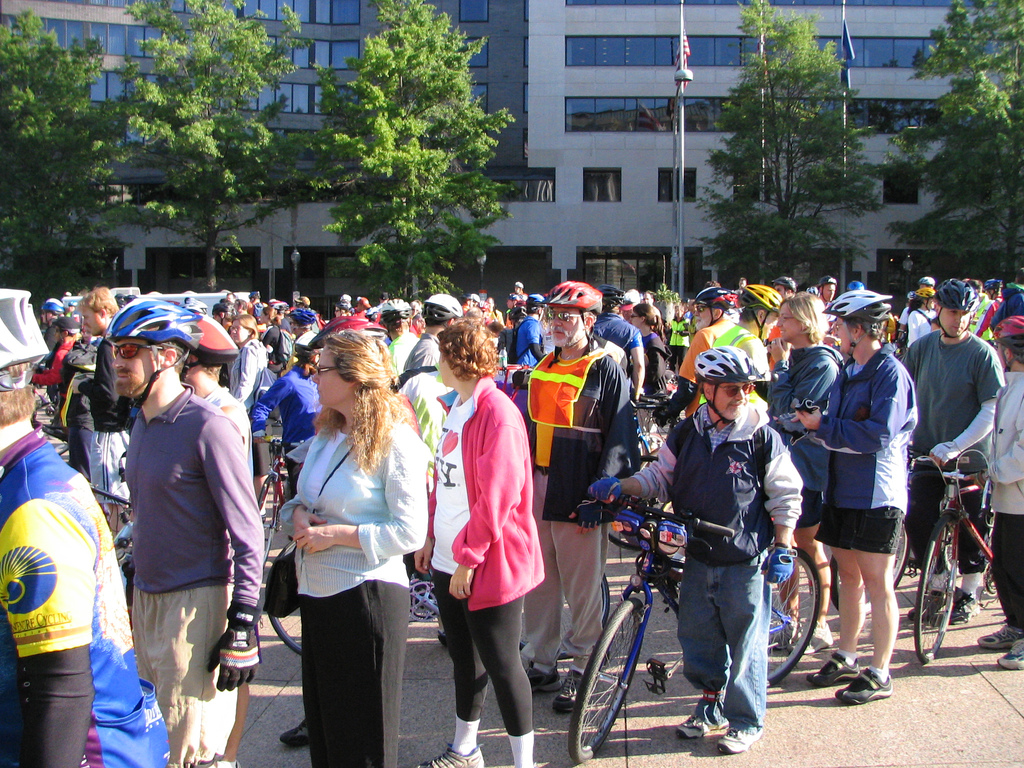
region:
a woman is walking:
[419, 322, 546, 766]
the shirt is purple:
[122, 390, 260, 603]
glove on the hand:
[210, 603, 259, 689]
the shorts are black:
[819, 501, 903, 556]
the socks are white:
[453, 717, 537, 766]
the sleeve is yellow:
[0, 504, 95, 656]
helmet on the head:
[105, 298, 198, 346]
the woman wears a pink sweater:
[424, 388, 545, 608]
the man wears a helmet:
[104, 303, 206, 352]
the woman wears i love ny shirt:
[426, 397, 474, 576]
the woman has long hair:
[325, 335, 411, 468]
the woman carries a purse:
[256, 436, 374, 617]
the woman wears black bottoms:
[306, 584, 409, 765]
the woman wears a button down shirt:
[277, 421, 421, 599]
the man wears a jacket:
[606, 424, 797, 561]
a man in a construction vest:
[522, 279, 640, 706]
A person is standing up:
[634, 333, 786, 746]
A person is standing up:
[784, 256, 930, 718]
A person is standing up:
[759, 282, 832, 678]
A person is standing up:
[410, 329, 557, 762]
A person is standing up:
[520, 272, 631, 702]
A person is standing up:
[274, 333, 418, 752]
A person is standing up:
[84, 296, 262, 764]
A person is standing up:
[375, 295, 414, 382]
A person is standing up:
[403, 292, 448, 384]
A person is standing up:
[511, 292, 546, 376]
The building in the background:
[26, 67, 1022, 273]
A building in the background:
[8, 69, 982, 278]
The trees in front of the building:
[5, 66, 1008, 278]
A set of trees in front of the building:
[11, 61, 1021, 242]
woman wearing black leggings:
[439, 590, 567, 721]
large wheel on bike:
[559, 568, 681, 766]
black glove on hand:
[177, 601, 273, 704]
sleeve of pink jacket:
[432, 398, 563, 621]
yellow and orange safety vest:
[521, 348, 616, 469]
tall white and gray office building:
[270, 0, 959, 283]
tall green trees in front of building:
[41, 7, 555, 260]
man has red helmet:
[479, 271, 663, 478]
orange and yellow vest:
[479, 320, 604, 533]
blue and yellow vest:
[0, 464, 298, 765]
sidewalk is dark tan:
[792, 680, 996, 761]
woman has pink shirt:
[245, 402, 599, 641]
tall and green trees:
[73, 25, 1020, 291]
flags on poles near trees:
[623, 7, 865, 264]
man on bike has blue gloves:
[734, 534, 821, 621]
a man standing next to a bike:
[566, 345, 792, 757]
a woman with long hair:
[320, 343, 404, 467]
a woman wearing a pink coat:
[468, 392, 548, 652]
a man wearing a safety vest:
[525, 351, 611, 425]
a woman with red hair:
[437, 319, 495, 367]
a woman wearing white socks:
[425, 716, 556, 761]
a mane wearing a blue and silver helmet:
[105, 305, 203, 363]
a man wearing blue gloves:
[768, 542, 801, 582]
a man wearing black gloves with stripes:
[204, 623, 262, 688]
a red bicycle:
[917, 460, 995, 644]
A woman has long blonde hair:
[295, 308, 429, 480]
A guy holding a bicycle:
[547, 327, 841, 757]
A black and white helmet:
[813, 275, 897, 334]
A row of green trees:
[0, 0, 1018, 311]